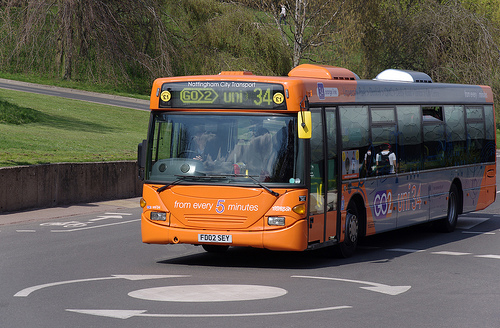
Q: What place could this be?
A: It is a road.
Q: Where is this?
A: This is at the road.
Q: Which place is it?
A: It is a road.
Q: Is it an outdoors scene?
A: Yes, it is outdoors.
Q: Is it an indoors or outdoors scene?
A: It is outdoors.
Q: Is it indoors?
A: No, it is outdoors.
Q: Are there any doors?
A: Yes, there is a door.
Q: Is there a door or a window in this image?
A: Yes, there is a door.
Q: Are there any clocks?
A: No, there are no clocks.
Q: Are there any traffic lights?
A: No, there are no traffic lights.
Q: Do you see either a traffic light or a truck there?
A: No, there are no traffic lights or trucks.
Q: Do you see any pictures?
A: No, there are no pictures.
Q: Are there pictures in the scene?
A: No, there are no pictures.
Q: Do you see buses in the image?
A: Yes, there is a bus.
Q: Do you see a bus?
A: Yes, there is a bus.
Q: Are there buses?
A: Yes, there is a bus.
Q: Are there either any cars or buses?
A: Yes, there is a bus.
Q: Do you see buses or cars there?
A: Yes, there is a bus.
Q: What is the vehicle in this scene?
A: The vehicle is a bus.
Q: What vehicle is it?
A: The vehicle is a bus.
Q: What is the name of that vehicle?
A: This is a bus.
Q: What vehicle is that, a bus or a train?
A: This is a bus.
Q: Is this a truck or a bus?
A: This is a bus.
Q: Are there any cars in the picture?
A: No, there are no cars.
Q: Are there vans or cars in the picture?
A: No, there are no cars or vans.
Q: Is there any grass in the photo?
A: Yes, there is grass.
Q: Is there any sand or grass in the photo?
A: Yes, there is grass.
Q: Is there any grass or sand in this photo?
A: Yes, there is grass.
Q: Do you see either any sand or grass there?
A: Yes, there is grass.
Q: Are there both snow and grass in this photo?
A: No, there is grass but no snow.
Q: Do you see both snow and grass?
A: No, there is grass but no snow.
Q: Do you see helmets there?
A: No, there are no helmets.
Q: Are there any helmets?
A: No, there are no helmets.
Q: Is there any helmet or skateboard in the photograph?
A: No, there are no helmets or skateboards.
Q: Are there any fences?
A: No, there are no fences.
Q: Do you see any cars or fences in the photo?
A: No, there are no fences or cars.